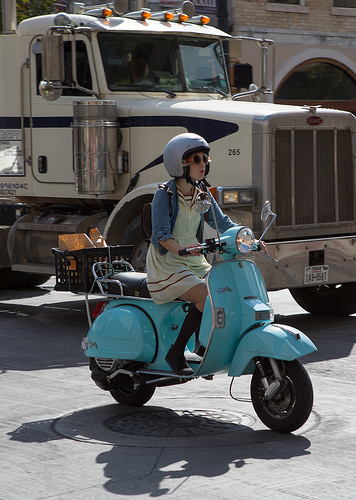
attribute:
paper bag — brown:
[57, 232, 95, 251]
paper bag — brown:
[90, 227, 107, 247]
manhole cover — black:
[101, 404, 257, 445]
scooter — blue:
[71, 241, 320, 442]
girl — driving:
[150, 133, 223, 203]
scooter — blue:
[104, 273, 236, 384]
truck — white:
[7, 12, 354, 333]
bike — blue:
[77, 233, 355, 370]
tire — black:
[248, 353, 314, 432]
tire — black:
[100, 348, 156, 404]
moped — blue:
[79, 197, 317, 432]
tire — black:
[88, 345, 154, 411]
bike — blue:
[63, 200, 317, 442]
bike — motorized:
[84, 168, 323, 429]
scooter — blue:
[78, 199, 318, 433]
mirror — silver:
[191, 189, 212, 220]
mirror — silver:
[260, 198, 273, 231]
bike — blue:
[107, 276, 182, 377]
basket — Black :
[51, 232, 154, 299]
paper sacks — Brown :
[58, 225, 104, 264]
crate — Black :
[54, 242, 136, 297]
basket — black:
[51, 238, 115, 277]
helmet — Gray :
[161, 133, 211, 179]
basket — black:
[52, 245, 131, 291]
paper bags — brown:
[59, 227, 108, 284]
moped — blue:
[50, 190, 319, 434]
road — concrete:
[0, 270, 330, 498]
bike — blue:
[52, 190, 318, 432]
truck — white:
[0, 0, 345, 317]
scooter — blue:
[40, 196, 319, 440]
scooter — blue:
[83, 234, 316, 432]